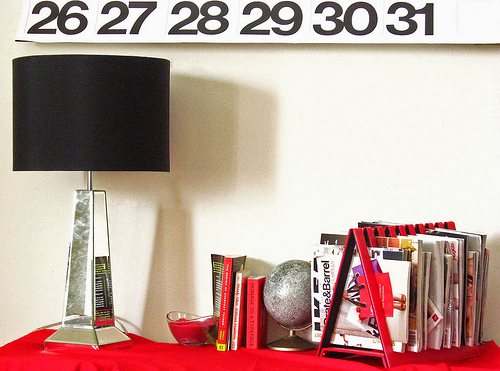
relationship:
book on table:
[229, 270, 249, 351] [35, 265, 496, 364]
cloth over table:
[146, 347, 176, 367] [2, 327, 496, 368]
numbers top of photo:
[25, 0, 445, 37] [19, 4, 499, 74]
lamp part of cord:
[16, 55, 172, 351] [40, 321, 60, 331]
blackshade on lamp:
[9, 49, 176, 178] [44, 171, 145, 346]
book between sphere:
[244, 272, 260, 352] [263, 259, 311, 326]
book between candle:
[244, 272, 260, 352] [166, 311, 218, 347]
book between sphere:
[229, 267, 245, 340] [263, 259, 311, 326]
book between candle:
[229, 267, 245, 340] [166, 311, 218, 347]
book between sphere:
[208, 252, 251, 345] [263, 259, 311, 326]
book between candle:
[208, 252, 251, 345] [166, 311, 218, 347]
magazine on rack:
[310, 219, 490, 353] [316, 219, 483, 369]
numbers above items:
[221, 0, 429, 42] [6, 53, 494, 368]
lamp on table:
[16, 55, 172, 351] [2, 327, 496, 368]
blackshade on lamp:
[11, 55, 170, 172] [4, 33, 232, 347]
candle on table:
[144, 289, 239, 350] [3, 320, 498, 368]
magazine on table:
[318, 252, 412, 347] [2, 327, 496, 368]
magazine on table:
[462, 249, 479, 346] [2, 327, 496, 368]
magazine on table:
[387, 236, 429, 353] [2, 327, 496, 368]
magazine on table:
[418, 234, 449, 351] [2, 327, 496, 368]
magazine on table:
[430, 223, 490, 344] [2, 327, 496, 368]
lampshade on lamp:
[13, 54, 170, 174] [16, 55, 172, 351]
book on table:
[245, 272, 267, 350] [2, 327, 496, 368]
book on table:
[210, 254, 245, 352] [2, 327, 496, 368]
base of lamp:
[53, 177, 128, 366] [16, 55, 172, 351]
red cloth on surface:
[5, 325, 495, 367] [66, 290, 287, 365]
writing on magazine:
[316, 262, 334, 321] [314, 255, 334, 321]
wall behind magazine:
[306, 159, 429, 209] [378, 259, 403, 336]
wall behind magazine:
[306, 159, 429, 209] [375, 245, 407, 261]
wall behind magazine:
[306, 159, 429, 209] [406, 255, 423, 314]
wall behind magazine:
[306, 159, 429, 209] [431, 265, 440, 301]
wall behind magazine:
[306, 159, 429, 209] [441, 267, 453, 287]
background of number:
[18, 1, 452, 38] [306, 9, 376, 32]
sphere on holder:
[264, 258, 313, 323] [266, 308, 313, 350]